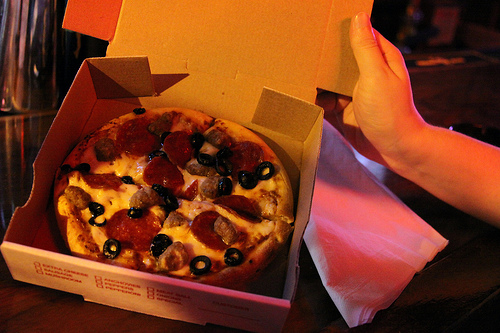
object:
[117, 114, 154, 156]
pepperoni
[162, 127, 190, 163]
pepperoni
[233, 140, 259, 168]
pepperoni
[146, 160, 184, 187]
pepperoni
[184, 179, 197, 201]
pepperoni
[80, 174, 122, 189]
pepperoni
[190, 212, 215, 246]
pepperoni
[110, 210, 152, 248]
pepperoni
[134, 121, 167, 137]
olive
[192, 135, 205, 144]
olive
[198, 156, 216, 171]
olive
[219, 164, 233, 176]
olive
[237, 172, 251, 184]
olive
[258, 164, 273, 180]
olive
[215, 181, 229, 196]
olive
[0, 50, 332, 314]
box